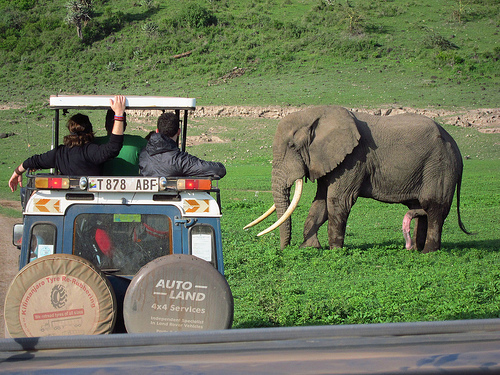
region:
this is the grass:
[305, 255, 420, 316]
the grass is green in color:
[328, 268, 415, 310]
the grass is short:
[286, 268, 397, 295]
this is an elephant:
[242, 108, 473, 262]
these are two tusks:
[243, 173, 306, 241]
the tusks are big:
[241, 180, 303, 235]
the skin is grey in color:
[364, 133, 391, 160]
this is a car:
[4, 85, 233, 335]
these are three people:
[4, 108, 219, 184]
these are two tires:
[3, 247, 236, 332]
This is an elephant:
[243, 90, 482, 258]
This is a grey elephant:
[239, 96, 486, 258]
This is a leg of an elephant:
[323, 174, 365, 254]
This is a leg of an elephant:
[302, 174, 329, 258]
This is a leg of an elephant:
[424, 179, 446, 257]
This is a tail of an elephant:
[452, 144, 480, 244]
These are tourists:
[6, 64, 241, 334]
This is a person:
[145, 102, 235, 184]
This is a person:
[100, 92, 146, 172]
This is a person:
[9, 92, 126, 201]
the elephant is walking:
[212, 69, 467, 274]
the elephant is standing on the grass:
[237, 85, 476, 287]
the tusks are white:
[236, 160, 304, 242]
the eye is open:
[268, 120, 305, 161]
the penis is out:
[385, 190, 447, 260]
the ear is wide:
[292, 99, 374, 184]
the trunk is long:
[259, 167, 291, 256]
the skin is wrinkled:
[256, 143, 305, 254]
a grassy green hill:
[200, 0, 479, 117]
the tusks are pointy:
[239, 210, 292, 252]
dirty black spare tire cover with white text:
[122, 254, 232, 333]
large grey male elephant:
[242, 105, 476, 251]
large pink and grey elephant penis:
[401, 209, 425, 249]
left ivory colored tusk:
[257, 177, 302, 235]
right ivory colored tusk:
[242, 202, 274, 228]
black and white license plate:
[88, 177, 158, 192]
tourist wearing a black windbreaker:
[137, 112, 225, 179]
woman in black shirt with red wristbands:
[8, 96, 125, 190]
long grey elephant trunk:
[272, 140, 304, 249]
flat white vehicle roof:
[48, 95, 195, 109]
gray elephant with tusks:
[241, 105, 474, 257]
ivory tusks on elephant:
[243, 177, 303, 239]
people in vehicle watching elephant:
[9, 95, 227, 196]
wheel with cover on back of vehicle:
[123, 253, 235, 335]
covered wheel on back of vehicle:
[4, 252, 118, 332]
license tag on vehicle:
[78, 175, 163, 193]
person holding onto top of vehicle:
[7, 96, 124, 193]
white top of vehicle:
[47, 90, 197, 112]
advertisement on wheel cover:
[146, 276, 211, 316]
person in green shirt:
[103, 110, 146, 176]